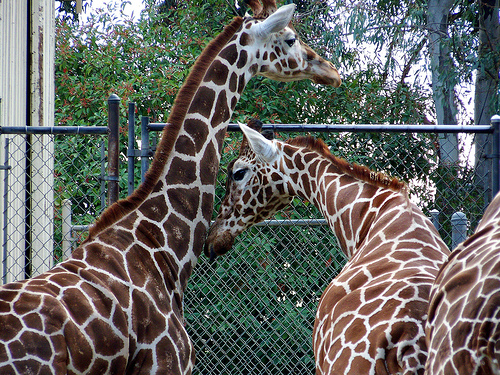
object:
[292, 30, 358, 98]
snout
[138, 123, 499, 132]
bar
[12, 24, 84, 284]
structure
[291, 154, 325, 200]
patch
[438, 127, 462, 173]
ground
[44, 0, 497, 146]
plants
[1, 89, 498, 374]
fence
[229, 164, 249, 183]
eye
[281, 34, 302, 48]
eye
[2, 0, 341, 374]
giraffe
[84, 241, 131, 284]
patch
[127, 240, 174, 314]
patch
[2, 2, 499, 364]
day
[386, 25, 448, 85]
sky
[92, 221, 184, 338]
brown spots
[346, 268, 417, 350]
brown spots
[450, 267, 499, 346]
brown spots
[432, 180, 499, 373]
giraffe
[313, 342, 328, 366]
patch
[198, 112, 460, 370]
giaffe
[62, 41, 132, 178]
trees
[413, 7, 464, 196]
trees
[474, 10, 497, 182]
trees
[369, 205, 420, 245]
patch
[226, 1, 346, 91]
head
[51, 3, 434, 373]
trees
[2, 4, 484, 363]
giraffes